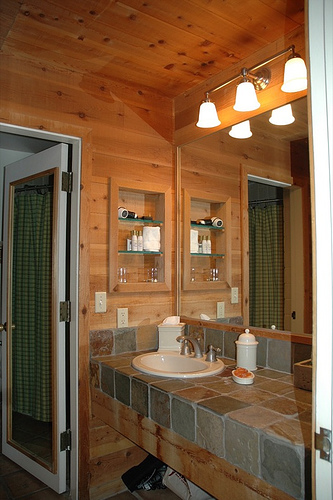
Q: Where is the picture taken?
A: Bathroom.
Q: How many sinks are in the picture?
A: One.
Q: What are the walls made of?
A: Wood.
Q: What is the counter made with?
A: Stone tiles.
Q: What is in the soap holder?
A: Soap.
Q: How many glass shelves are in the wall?
A: Two.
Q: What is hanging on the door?
A: Mirror.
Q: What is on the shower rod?
A: Shower curtain.